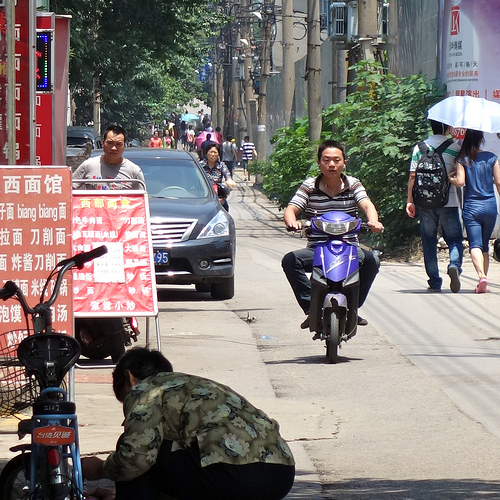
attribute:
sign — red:
[17, 165, 68, 260]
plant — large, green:
[306, 46, 441, 226]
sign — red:
[2, 163, 79, 402]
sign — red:
[58, 172, 172, 329]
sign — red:
[1, 159, 82, 385]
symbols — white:
[0, 173, 67, 332]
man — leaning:
[80, 347, 295, 499]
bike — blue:
[0, 243, 109, 498]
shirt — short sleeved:
[284, 170, 373, 244]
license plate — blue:
[153, 251, 167, 266]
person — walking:
[448, 128, 499, 292]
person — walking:
[403, 119, 466, 289]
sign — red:
[26, 174, 41, 191]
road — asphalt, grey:
[190, 143, 498, 497]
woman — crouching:
[95, 345, 301, 495]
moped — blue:
[271, 198, 413, 383]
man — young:
[407, 116, 467, 292]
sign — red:
[1, 155, 79, 362]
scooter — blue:
[274, 204, 381, 352]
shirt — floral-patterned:
[108, 364, 296, 474]